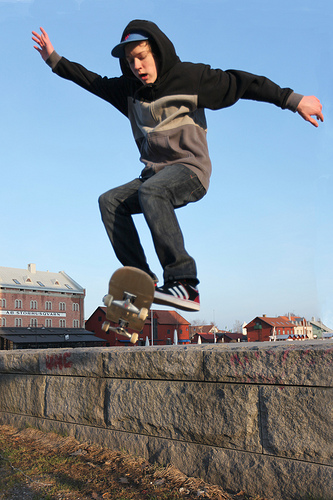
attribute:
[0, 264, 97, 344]
building — large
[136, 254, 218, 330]
shoe — red white and black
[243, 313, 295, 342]
building — red, large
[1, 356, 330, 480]
stone wall — short, brick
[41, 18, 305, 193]
sweatshirt — grey and black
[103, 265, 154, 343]
skateboard — beige